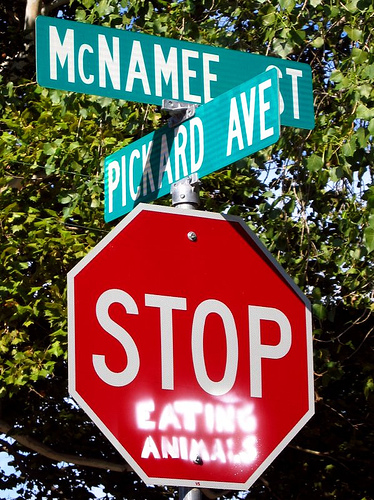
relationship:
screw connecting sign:
[189, 450, 208, 469] [62, 197, 316, 494]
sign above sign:
[99, 67, 285, 228] [62, 197, 316, 494]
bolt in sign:
[183, 223, 200, 245] [62, 197, 316, 494]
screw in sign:
[189, 450, 208, 469] [62, 197, 316, 494]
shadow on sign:
[132, 99, 185, 213] [62, 197, 316, 494]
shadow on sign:
[132, 99, 185, 213] [99, 67, 285, 228]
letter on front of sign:
[90, 281, 147, 391] [62, 197, 316, 494]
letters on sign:
[91, 281, 295, 402] [62, 197, 316, 494]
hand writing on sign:
[127, 392, 264, 479] [62, 197, 316, 494]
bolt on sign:
[183, 223, 200, 245] [62, 197, 316, 494]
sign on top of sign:
[99, 67, 285, 228] [33, 12, 321, 136]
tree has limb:
[4, 1, 373, 499] [3, 416, 135, 484]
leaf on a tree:
[305, 146, 331, 192] [4, 1, 373, 499]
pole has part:
[161, 96, 202, 499] [170, 188, 194, 206]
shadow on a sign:
[132, 99, 185, 213] [99, 67, 285, 228]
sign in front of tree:
[62, 197, 316, 494] [4, 1, 373, 499]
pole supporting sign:
[161, 96, 202, 499] [62, 197, 316, 494]